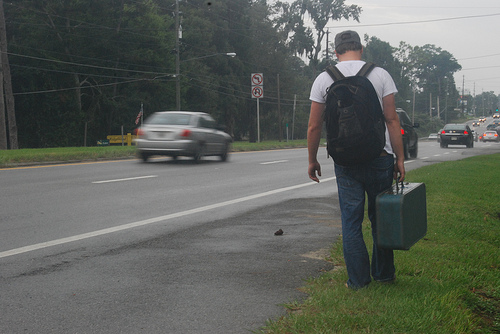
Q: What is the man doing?
A: Walking.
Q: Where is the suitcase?
A: In the man's hand.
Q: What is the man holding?
A: A suitcase.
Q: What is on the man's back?
A: Backpack.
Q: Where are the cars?
A: On the road.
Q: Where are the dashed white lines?
A: Middle of the road.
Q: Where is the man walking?
A: On the side of the road.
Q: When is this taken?
A: During the day.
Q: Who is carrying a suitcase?
A: A man.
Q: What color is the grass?
A: Green.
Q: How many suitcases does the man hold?
A: One.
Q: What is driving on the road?
A: A car.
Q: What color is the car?
A: Silver.